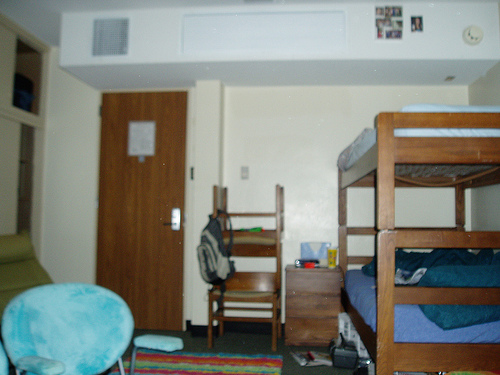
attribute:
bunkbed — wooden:
[324, 96, 498, 375]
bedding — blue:
[364, 235, 498, 328]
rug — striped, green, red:
[124, 344, 285, 375]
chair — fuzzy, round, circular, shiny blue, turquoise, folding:
[3, 275, 142, 374]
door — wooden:
[89, 83, 191, 342]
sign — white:
[119, 113, 161, 164]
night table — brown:
[283, 262, 342, 353]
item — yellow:
[322, 242, 343, 272]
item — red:
[299, 261, 321, 270]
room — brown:
[3, 4, 496, 370]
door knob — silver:
[155, 204, 184, 235]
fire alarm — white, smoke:
[459, 22, 488, 51]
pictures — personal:
[369, 2, 429, 45]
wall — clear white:
[60, 9, 499, 102]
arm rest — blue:
[101, 306, 141, 364]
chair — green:
[4, 222, 58, 283]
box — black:
[325, 325, 367, 370]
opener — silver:
[160, 215, 183, 230]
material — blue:
[29, 291, 109, 352]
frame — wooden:
[369, 116, 492, 368]